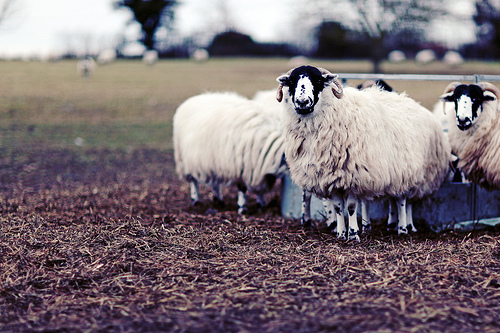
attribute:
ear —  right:
[275, 74, 290, 86]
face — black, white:
[442, 85, 490, 130]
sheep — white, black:
[272, 55, 445, 241]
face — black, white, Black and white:
[273, 63, 344, 120]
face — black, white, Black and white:
[282, 65, 323, 115]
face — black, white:
[452, 89, 478, 131]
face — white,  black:
[266, 53, 346, 118]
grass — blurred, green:
[3, 121, 172, 150]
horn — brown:
[267, 83, 294, 102]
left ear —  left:
[322, 71, 339, 87]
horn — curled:
[323, 67, 345, 97]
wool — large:
[283, 85, 450, 200]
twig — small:
[0, 198, 498, 331]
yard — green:
[14, 40, 246, 292]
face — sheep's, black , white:
[276, 66, 330, 116]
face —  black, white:
[438, 84, 492, 131]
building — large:
[197, 20, 297, 60]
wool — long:
[336, 146, 416, 203]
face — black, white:
[441, 80, 494, 131]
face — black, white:
[273, 60, 342, 116]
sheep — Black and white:
[276, 62, 447, 204]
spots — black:
[300, 195, 355, 216]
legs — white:
[297, 188, 415, 243]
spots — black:
[298, 84, 308, 98]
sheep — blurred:
[154, 45, 471, 266]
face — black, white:
[264, 61, 346, 113]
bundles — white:
[372, 40, 467, 79]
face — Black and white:
[282, 64, 332, 132]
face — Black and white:
[279, 66, 325, 108]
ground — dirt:
[119, 230, 396, 312]